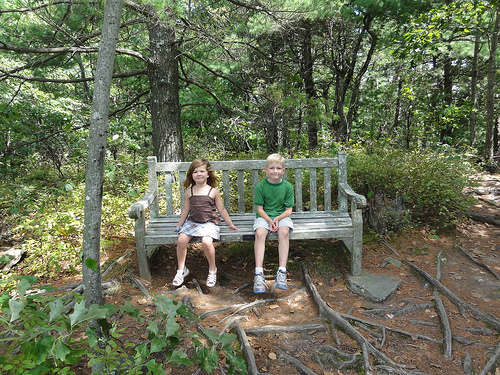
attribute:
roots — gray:
[1, 162, 498, 373]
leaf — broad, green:
[61, 298, 111, 332]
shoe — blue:
[254, 273, 265, 295]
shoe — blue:
[274, 269, 286, 289]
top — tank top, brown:
[186, 185, 216, 222]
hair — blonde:
[263, 155, 285, 170]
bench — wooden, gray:
[103, 113, 407, 311]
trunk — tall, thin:
[75, 1, 125, 310]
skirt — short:
[173, 221, 218, 243]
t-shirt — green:
[237, 147, 304, 224]